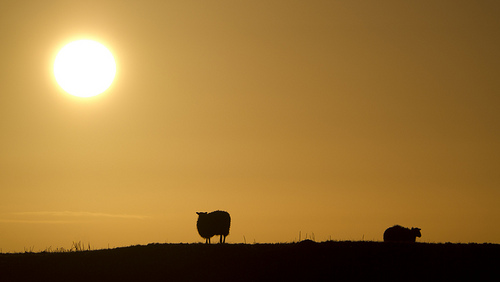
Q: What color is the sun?
A: Yellow.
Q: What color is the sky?
A: Hazy yellow.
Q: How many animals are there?
A: 2.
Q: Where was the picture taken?
A: In a pasture.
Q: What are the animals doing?
A: Standing and sitting.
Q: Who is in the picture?
A: 2 sheet.